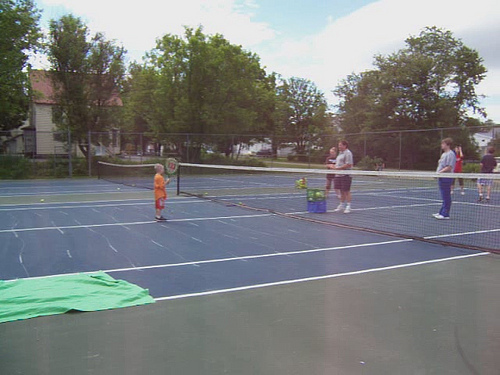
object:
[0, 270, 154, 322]
blanket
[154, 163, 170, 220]
boy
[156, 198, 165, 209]
red shorts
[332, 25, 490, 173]
trees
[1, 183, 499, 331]
court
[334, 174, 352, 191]
shorts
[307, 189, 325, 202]
basket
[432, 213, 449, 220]
shoes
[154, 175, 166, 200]
shirt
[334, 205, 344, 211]
shoe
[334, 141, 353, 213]
adults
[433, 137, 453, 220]
adults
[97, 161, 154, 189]
net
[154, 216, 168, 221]
shoe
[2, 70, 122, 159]
building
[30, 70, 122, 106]
shingled roof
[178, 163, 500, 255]
net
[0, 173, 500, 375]
tennis court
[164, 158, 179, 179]
racket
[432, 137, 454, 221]
man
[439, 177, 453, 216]
jeans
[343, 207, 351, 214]
shoe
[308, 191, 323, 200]
balls